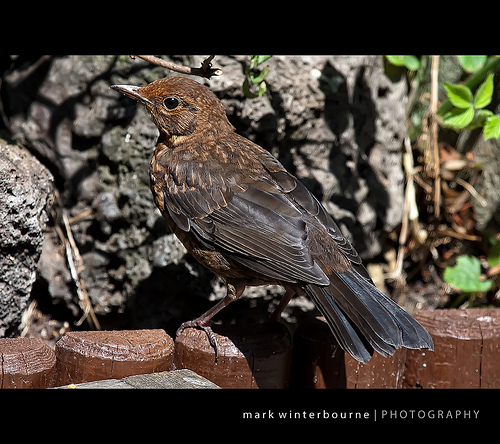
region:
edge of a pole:
[109, 335, 145, 360]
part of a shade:
[248, 321, 290, 398]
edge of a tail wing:
[348, 318, 418, 383]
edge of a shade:
[229, 340, 271, 402]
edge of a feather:
[258, 258, 296, 286]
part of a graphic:
[347, 381, 429, 423]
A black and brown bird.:
[109, 73, 436, 367]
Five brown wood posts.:
[0, 305, 499, 390]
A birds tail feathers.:
[297, 263, 436, 367]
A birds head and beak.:
[110, 76, 238, 145]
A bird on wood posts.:
[109, 74, 435, 367]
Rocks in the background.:
[2, 55, 497, 338]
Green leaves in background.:
[383, 53, 498, 306]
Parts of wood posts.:
[0, 327, 175, 390]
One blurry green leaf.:
[442, 252, 494, 293]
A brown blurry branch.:
[426, 55, 444, 220]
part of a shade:
[231, 290, 274, 371]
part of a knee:
[220, 275, 249, 317]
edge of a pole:
[434, 332, 482, 353]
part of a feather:
[273, 254, 328, 304]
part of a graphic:
[343, 398, 392, 434]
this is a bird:
[115, 60, 355, 350]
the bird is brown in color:
[107, 62, 360, 342]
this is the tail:
[312, 267, 434, 352]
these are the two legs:
[175, 291, 290, 341]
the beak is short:
[106, 80, 138, 96]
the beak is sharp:
[106, 80, 141, 96]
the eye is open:
[165, 95, 178, 107]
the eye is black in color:
[165, 96, 180, 106]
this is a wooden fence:
[70, 328, 160, 368]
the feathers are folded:
[244, 198, 316, 243]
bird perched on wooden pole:
[26, 55, 472, 371]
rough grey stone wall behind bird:
[20, 51, 440, 296]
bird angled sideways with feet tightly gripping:
[90, 55, 445, 370]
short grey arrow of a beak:
[95, 65, 275, 191]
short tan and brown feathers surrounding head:
[135, 72, 230, 152]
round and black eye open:
[155, 81, 190, 118]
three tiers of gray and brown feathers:
[141, 135, 441, 360]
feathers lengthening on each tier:
[141, 130, 451, 360]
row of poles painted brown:
[5, 305, 491, 377]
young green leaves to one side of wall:
[392, 48, 497, 291]